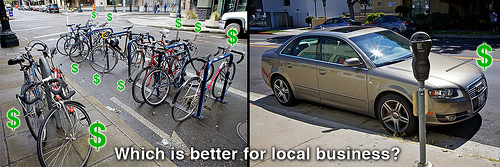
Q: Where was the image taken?
A: It was taken at the street.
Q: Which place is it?
A: It is a street.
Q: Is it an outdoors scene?
A: Yes, it is outdoors.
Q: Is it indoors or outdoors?
A: It is outdoors.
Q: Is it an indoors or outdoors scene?
A: It is outdoors.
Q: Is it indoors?
A: No, it is outdoors.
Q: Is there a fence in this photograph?
A: No, there are no fences.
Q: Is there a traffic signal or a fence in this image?
A: No, there are no fences or traffic lights.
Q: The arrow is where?
A: The arrow is on the street.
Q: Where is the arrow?
A: The arrow is on the street.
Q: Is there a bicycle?
A: Yes, there is a bicycle.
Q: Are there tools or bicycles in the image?
A: Yes, there is a bicycle.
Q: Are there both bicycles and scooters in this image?
A: No, there is a bicycle but no scooters.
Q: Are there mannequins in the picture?
A: No, there are no mannequins.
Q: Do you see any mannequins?
A: No, there are no mannequins.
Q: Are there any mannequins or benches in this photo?
A: No, there are no mannequins or benches.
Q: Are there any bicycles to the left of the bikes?
A: Yes, there is a bicycle to the left of the bikes.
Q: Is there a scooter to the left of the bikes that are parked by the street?
A: No, there is a bicycle to the left of the bikes.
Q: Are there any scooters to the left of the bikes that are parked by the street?
A: No, there is a bicycle to the left of the bikes.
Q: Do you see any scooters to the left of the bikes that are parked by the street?
A: No, there is a bicycle to the left of the bikes.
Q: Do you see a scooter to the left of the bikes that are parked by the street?
A: No, there is a bicycle to the left of the bikes.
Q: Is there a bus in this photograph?
A: No, there are no buses.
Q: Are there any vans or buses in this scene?
A: No, there are no buses or vans.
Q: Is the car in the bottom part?
A: No, the car is in the top of the image.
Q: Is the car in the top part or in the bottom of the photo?
A: The car is in the top of the image.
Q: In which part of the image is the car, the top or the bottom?
A: The car is in the top of the image.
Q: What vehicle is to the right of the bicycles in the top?
A: The vehicle is a car.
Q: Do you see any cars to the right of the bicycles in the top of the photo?
A: Yes, there is a car to the right of the bicycles.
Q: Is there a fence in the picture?
A: No, there are no fences.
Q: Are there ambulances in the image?
A: No, there are no ambulances.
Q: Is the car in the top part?
A: Yes, the car is in the top of the image.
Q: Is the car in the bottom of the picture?
A: No, the car is in the top of the image.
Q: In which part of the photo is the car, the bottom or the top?
A: The car is in the top of the image.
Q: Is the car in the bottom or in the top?
A: The car is in the top of the image.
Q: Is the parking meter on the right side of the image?
A: Yes, the parking meter is on the right of the image.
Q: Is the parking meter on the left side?
A: No, the parking meter is on the right of the image.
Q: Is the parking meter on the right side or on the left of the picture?
A: The parking meter is on the right of the image.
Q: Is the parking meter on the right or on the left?
A: The parking meter is on the right of the image.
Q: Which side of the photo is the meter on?
A: The meter is on the right of the image.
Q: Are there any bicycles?
A: Yes, there are bicycles.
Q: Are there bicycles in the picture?
A: Yes, there are bicycles.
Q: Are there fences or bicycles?
A: Yes, there are bicycles.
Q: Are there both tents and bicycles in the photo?
A: No, there are bicycles but no tents.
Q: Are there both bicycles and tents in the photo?
A: No, there are bicycles but no tents.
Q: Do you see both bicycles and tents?
A: No, there are bicycles but no tents.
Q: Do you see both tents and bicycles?
A: No, there are bicycles but no tents.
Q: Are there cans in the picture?
A: No, there are no cans.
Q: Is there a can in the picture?
A: No, there are no cans.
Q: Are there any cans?
A: No, there are no cans.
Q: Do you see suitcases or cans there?
A: No, there are no cans or suitcases.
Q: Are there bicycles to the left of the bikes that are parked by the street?
A: Yes, there are bicycles to the left of the bikes.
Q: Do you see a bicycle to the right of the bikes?
A: No, the bicycles are to the left of the bikes.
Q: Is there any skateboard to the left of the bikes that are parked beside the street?
A: No, there are bicycles to the left of the bikes.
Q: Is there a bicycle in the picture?
A: Yes, there is a bicycle.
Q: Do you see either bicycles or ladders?
A: Yes, there is a bicycle.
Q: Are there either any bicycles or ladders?
A: Yes, there is a bicycle.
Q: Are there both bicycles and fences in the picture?
A: No, there is a bicycle but no fences.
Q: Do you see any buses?
A: No, there are no buses.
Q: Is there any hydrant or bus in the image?
A: No, there are no buses or fire hydrants.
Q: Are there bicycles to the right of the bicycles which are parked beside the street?
A: Yes, there is a bicycle to the right of the bikes.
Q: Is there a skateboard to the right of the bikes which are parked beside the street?
A: No, there is a bicycle to the right of the bikes.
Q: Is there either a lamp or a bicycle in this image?
A: Yes, there is a bicycle.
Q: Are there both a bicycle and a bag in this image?
A: No, there is a bicycle but no bags.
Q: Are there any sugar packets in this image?
A: No, there are no sugar packets.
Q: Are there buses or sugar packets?
A: No, there are no sugar packets or buses.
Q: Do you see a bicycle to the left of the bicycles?
A: Yes, there is a bicycle to the left of the bicycles.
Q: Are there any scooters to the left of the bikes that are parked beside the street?
A: No, there is a bicycle to the left of the bikes.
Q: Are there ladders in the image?
A: No, there are no ladders.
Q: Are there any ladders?
A: No, there are no ladders.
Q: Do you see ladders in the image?
A: No, there are no ladders.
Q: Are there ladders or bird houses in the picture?
A: No, there are no ladders or bird houses.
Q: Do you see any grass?
A: Yes, there is grass.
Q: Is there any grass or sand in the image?
A: Yes, there is grass.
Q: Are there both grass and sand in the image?
A: No, there is grass but no sand.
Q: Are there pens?
A: No, there are no pens.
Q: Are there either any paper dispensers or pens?
A: No, there are no pens or paper dispensers.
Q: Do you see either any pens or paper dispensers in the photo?
A: No, there are no pens or paper dispensers.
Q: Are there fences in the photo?
A: No, there are no fences.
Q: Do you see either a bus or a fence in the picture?
A: No, there are no fences or buses.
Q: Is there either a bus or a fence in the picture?
A: No, there are no fences or buses.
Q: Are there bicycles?
A: Yes, there are bicycles.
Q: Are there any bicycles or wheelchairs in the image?
A: Yes, there are bicycles.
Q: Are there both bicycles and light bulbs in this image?
A: No, there are bicycles but no light bulbs.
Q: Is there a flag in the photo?
A: No, there are no flags.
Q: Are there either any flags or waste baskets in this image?
A: No, there are no flags or waste baskets.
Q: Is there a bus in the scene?
A: No, there are no buses.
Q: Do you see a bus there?
A: No, there are no buses.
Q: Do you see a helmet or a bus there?
A: No, there are no buses or helmets.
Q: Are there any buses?
A: No, there are no buses.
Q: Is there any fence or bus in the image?
A: No, there are no buses or fences.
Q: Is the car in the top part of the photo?
A: Yes, the car is in the top of the image.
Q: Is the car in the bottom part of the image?
A: No, the car is in the top of the image.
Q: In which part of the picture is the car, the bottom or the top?
A: The car is in the top of the image.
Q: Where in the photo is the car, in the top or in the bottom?
A: The car is in the top of the image.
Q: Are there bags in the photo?
A: No, there are no bags.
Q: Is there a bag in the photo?
A: No, there are no bags.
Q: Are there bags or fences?
A: No, there are no bags or fences.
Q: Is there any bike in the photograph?
A: Yes, there are bikes.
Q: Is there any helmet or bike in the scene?
A: Yes, there are bikes.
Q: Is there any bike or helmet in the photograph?
A: Yes, there are bikes.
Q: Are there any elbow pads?
A: No, there are no elbow pads.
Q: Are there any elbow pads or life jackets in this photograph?
A: No, there are no elbow pads or life jackets.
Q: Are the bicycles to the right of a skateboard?
A: No, the bicycles are to the right of a bicycle.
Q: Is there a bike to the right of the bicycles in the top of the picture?
A: Yes, there are bikes to the right of the bicycles.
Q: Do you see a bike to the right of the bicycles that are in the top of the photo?
A: Yes, there are bikes to the right of the bicycles.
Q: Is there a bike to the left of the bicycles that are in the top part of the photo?
A: No, the bikes are to the right of the bicycles.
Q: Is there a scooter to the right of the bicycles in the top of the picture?
A: No, there are bikes to the right of the bicycles.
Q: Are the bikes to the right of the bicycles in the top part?
A: Yes, the bikes are to the right of the bicycles.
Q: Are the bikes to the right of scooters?
A: No, the bikes are to the right of the bicycles.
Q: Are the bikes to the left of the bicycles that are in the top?
A: No, the bikes are to the right of the bicycles.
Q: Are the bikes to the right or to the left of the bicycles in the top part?
A: The bikes are to the right of the bicycles.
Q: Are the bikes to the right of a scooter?
A: No, the bikes are to the right of a bicycle.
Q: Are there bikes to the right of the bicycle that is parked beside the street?
A: Yes, there are bikes to the right of the bicycle.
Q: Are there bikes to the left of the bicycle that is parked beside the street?
A: No, the bikes are to the right of the bicycle.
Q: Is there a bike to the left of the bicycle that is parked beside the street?
A: No, the bikes are to the right of the bicycle.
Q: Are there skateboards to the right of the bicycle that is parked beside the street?
A: No, there are bikes to the right of the bicycle.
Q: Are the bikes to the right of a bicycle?
A: Yes, the bikes are to the right of a bicycle.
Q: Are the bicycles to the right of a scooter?
A: No, the bicycles are to the right of a bicycle.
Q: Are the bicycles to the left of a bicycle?
A: No, the bicycles are to the right of a bicycle.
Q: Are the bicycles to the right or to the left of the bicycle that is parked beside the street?
A: The bicycles are to the right of the bicycle.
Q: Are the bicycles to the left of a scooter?
A: No, the bicycles are to the left of a bicycle.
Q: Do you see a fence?
A: No, there are no fences.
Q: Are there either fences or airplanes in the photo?
A: No, there are no fences or airplanes.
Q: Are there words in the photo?
A: Yes, there are words.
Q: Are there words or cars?
A: Yes, there are words.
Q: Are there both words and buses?
A: No, there are words but no buses.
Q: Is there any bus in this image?
A: No, there are no buses.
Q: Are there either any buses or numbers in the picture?
A: No, there are no buses or numbers.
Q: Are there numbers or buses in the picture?
A: No, there are no buses or numbers.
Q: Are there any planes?
A: No, there are no planes.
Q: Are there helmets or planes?
A: No, there are no planes or helmets.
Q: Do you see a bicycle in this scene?
A: Yes, there is a bicycle.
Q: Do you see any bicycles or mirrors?
A: Yes, there is a bicycle.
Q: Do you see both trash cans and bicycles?
A: No, there is a bicycle but no trash cans.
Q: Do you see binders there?
A: No, there are no binders.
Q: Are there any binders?
A: No, there are no binders.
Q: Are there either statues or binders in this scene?
A: No, there are no binders or statues.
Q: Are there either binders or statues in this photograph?
A: No, there are no binders or statues.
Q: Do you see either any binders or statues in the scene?
A: No, there are no binders or statues.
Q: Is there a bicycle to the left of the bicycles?
A: Yes, there is a bicycle to the left of the bicycles.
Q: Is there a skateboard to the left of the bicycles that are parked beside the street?
A: No, there is a bicycle to the left of the bicycles.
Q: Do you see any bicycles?
A: Yes, there is a bicycle.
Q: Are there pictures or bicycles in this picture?
A: Yes, there is a bicycle.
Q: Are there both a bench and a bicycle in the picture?
A: No, there is a bicycle but no benches.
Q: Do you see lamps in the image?
A: No, there are no lamps.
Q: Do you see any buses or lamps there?
A: No, there are no lamps or buses.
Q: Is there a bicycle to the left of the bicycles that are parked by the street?
A: Yes, there is a bicycle to the left of the bicycles.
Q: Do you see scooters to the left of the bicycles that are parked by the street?
A: No, there is a bicycle to the left of the bicycles.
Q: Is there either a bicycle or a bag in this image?
A: Yes, there is a bicycle.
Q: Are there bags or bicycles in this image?
A: Yes, there is a bicycle.